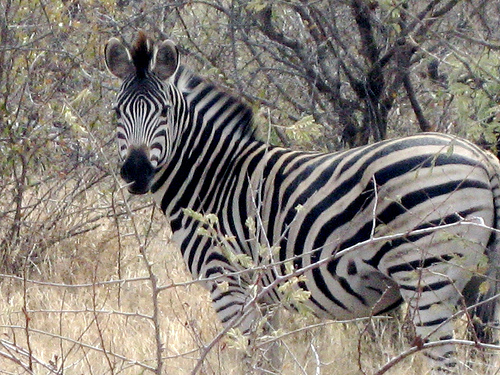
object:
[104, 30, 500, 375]
zebra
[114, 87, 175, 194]
face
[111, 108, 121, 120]
eye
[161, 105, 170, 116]
eye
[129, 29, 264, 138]
mane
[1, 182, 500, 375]
grass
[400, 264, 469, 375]
leg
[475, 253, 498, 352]
leg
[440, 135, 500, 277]
rump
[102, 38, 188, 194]
head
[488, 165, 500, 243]
tail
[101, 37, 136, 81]
ear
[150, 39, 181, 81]
ear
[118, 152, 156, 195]
snout